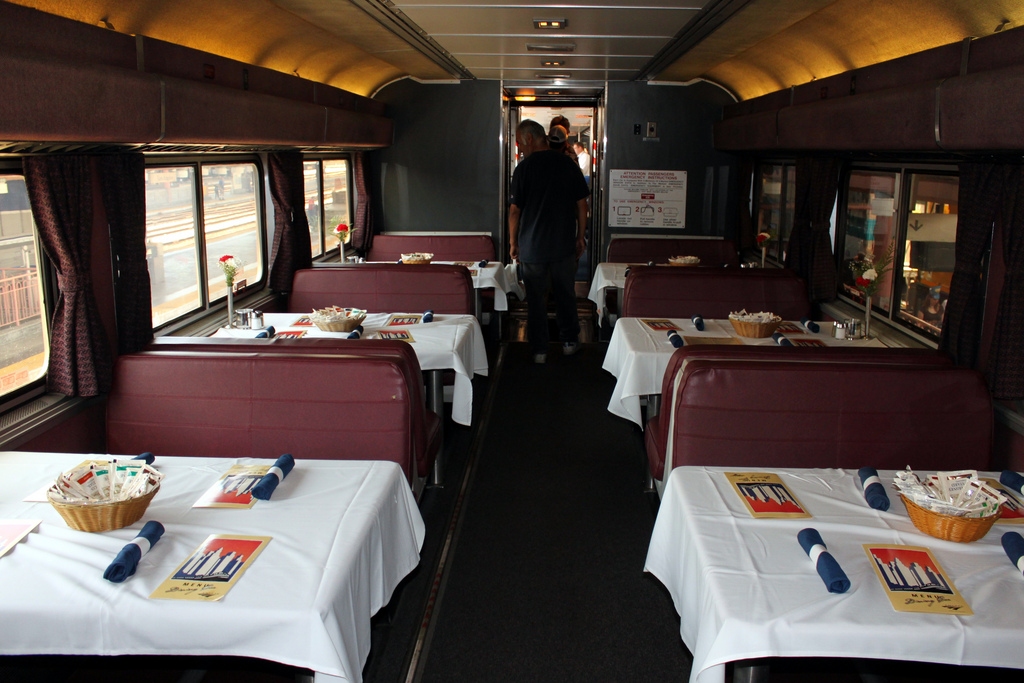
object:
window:
[0, 173, 60, 418]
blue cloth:
[102, 520, 163, 583]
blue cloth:
[797, 527, 851, 593]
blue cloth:
[250, 453, 294, 500]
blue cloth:
[859, 465, 891, 510]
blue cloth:
[1000, 531, 1024, 574]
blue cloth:
[1000, 470, 1024, 494]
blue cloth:
[131, 452, 155, 465]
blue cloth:
[666, 329, 683, 348]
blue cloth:
[424, 309, 435, 323]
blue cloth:
[347, 325, 364, 339]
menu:
[862, 544, 972, 615]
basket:
[47, 459, 160, 532]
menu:
[150, 534, 274, 601]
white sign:
[608, 168, 687, 228]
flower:
[217, 254, 242, 325]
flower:
[337, 223, 348, 232]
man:
[509, 119, 591, 363]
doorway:
[507, 101, 598, 299]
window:
[299, 150, 353, 262]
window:
[143, 151, 267, 340]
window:
[837, 154, 961, 350]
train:
[0, 0, 1024, 683]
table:
[643, 465, 1024, 683]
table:
[0, 450, 425, 683]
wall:
[603, 80, 738, 262]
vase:
[228, 285, 234, 328]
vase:
[340, 240, 345, 262]